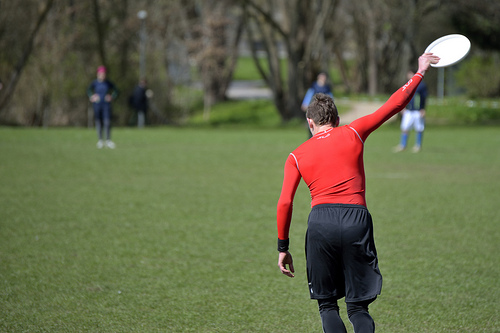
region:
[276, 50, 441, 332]
A guy in a long sleeve red shirt and black shorts.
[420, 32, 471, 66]
A white frisbee in a hand.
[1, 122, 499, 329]
A green trimmed grassy field.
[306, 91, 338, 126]
Brown hair on the head of a guy in red.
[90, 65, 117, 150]
A woman across the field in a pink hata and blue shirt.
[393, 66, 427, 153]
A person standing in blue socks and white shorts.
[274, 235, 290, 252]
A black Nike wrist band on a man's left hand.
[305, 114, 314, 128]
The left ear of a man in a red shirt.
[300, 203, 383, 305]
Black shorts on a guy holding a frisbee.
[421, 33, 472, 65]
White disc in a hand of a red shirt man.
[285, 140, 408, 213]
the shirt is red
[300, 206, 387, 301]
the short is black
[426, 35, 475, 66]
the frisbee is white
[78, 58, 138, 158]
the picture of the man is blurred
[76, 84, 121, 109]
the hands are akimbo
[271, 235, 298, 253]
the wristband is black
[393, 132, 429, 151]
the socks are blue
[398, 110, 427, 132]
the shorts are white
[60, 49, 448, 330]
five people are on the pitch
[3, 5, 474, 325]
it is daytime in the photo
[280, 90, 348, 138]
boy has brown hair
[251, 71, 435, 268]
boy has red shirt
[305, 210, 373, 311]
boy has black shorts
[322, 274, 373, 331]
boy has black socks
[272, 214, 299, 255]
boy has black wristband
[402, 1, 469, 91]
boy holds white frisbee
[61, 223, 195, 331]
green grass on field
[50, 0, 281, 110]
trees are in back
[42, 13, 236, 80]
brown leaves on trees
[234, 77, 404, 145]
grey path in back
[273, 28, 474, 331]
man in red shirt holding frisbee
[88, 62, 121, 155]
person with pink hat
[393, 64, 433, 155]
person in blue jeans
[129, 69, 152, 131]
person in black jacket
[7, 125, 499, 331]
field covered in green grass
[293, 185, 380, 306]
man in blue shorts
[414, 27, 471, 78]
white frisbee in man's hand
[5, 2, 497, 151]
trees in the distance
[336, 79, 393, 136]
dirt pathway through trees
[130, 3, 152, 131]
light pole near trees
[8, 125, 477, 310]
field where game is being played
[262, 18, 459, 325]
frisbee in the male's hand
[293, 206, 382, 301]
shorts worn by male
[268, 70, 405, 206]
shirt worn by male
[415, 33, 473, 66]
white frisbee in male's hand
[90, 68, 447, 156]
people on field playing game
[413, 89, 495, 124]
wild plants growing in field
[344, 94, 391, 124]
road near the field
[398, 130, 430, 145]
socks on the person